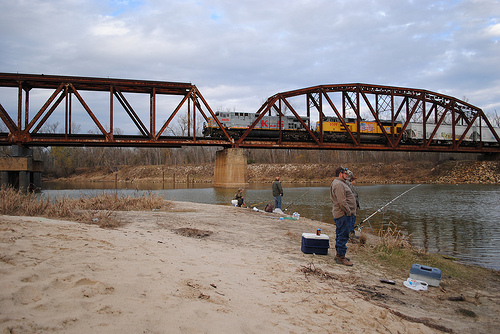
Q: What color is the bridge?
A: Red.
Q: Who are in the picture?
A: Three people.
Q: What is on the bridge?
A: Train.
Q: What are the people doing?
A: Fishing.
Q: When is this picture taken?
A: During the day.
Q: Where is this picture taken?
A: By a river.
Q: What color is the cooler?
A: Blue.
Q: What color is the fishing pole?
A: White.